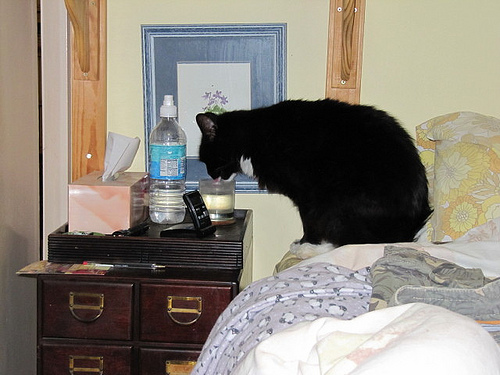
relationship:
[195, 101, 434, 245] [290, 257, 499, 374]
cat on top of bed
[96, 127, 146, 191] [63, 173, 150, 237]
tissue inside of box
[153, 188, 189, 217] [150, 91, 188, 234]
water inside of bottle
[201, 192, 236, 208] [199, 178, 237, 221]
water in glass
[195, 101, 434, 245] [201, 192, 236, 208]
cat drinking water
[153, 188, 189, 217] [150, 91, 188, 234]
water in bottle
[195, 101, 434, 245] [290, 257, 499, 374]
cat sitting on bed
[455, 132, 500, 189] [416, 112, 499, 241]
flowers on pillowcase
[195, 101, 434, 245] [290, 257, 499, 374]
cat on bed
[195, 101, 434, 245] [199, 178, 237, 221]
cat drinking from glass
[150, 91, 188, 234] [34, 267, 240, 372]
bottle on table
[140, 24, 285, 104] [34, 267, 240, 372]
frame above table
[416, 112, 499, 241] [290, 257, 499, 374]
pillowcase on bed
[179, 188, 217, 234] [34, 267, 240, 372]
clock on table